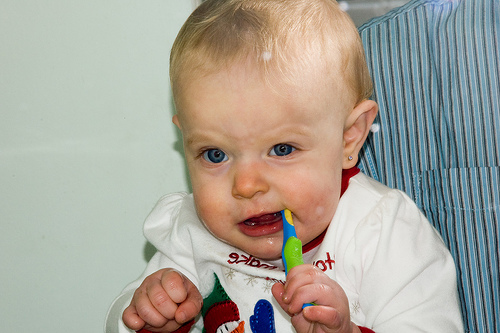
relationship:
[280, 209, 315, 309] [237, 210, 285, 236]
object in mouth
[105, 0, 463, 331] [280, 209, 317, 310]
baby holds object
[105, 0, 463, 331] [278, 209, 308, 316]
baby holds toothbrush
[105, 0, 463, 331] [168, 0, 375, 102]
baby wears hair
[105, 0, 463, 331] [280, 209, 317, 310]
baby holding object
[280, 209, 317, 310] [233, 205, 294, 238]
object in mouth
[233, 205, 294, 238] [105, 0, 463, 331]
mouth of baby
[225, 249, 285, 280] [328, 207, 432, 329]
writing on cloth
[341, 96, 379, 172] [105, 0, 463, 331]
ear of baby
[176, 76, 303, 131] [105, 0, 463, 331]
forehead of baby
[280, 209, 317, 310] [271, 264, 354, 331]
object in left hand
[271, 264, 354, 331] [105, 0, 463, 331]
left hand of baby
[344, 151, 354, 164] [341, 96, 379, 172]
earring in ear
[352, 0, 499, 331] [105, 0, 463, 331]
shirt behind baby